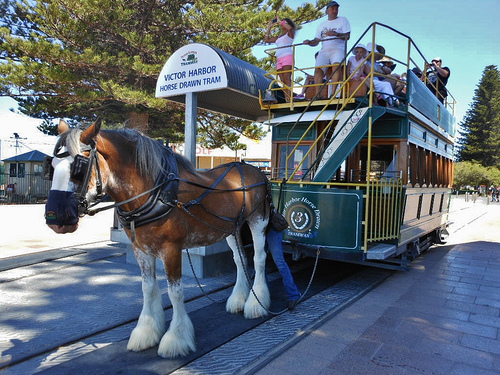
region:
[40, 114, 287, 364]
a brown and white clydesdale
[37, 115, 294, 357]
a large harnessed horse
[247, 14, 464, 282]
a green a yellow trolley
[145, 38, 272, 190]
a tram waiting station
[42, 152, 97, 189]
a pair of horse blinders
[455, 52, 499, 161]
a green tree in the distance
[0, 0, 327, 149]
a large green tree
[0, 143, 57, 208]
a building in the distance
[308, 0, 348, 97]
a person standing on a trolley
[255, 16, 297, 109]
a person standing on a trolley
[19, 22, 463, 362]
horse pulling a tram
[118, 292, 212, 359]
large hairy hooves of a Clydesdale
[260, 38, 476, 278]
tram on tracks being pulled by a horse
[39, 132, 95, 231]
black and white mask on a horse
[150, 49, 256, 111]
blue and white tram platform shelter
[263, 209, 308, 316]
person taking care of the horse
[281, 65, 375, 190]
stairway leading to the second story of the tram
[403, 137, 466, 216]
windows on the side of a tram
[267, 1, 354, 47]
people atop the tram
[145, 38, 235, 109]
semi circle sign with blue letters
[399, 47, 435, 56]
top of a bus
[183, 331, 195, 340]
foot of a horse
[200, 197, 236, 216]
body of a horse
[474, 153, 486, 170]
part of a foret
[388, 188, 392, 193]
door of a bus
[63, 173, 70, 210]
face of a horse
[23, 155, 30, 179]
part of a buillding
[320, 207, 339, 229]
part of a board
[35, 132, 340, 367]
the horse is brown and white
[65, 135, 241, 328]
the horse is brown and white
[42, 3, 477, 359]
Horse drawn tram with tourist.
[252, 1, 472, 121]
Top of tram filled with tourist.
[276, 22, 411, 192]
Stairs leading up to top of tram.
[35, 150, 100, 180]
Blinders on side of horse's eyes.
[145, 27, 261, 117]
Top of waiting station for tram rides.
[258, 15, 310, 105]
Woman standing on top of tram taking pictures.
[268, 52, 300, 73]
Woman dressed in pink shorts.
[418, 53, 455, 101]
Man in back dressed in black t-shirt taking pictures.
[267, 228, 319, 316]
Jean clad leg of person behind horse.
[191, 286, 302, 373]
Tracks for tram to travel on.